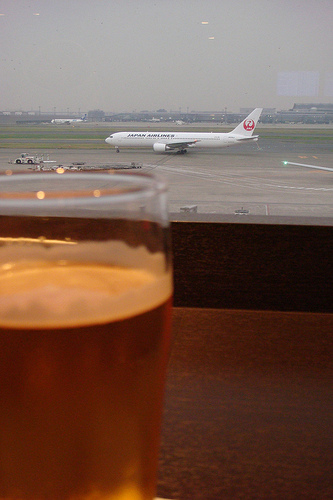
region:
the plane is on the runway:
[102, 113, 262, 160]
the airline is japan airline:
[114, 115, 260, 149]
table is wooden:
[200, 333, 314, 494]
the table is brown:
[207, 307, 317, 490]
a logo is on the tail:
[236, 115, 251, 131]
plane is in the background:
[34, 107, 91, 126]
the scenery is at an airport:
[17, 109, 320, 191]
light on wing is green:
[274, 155, 291, 165]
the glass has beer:
[4, 186, 173, 498]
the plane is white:
[102, 110, 262, 155]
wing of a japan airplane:
[219, 85, 332, 163]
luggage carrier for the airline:
[11, 142, 63, 163]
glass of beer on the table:
[13, 179, 198, 469]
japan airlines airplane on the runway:
[102, 103, 283, 172]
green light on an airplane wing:
[271, 146, 317, 197]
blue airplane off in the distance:
[12, 104, 111, 127]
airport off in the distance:
[84, 99, 233, 124]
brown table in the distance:
[185, 312, 297, 476]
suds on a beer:
[0, 249, 148, 317]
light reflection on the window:
[176, 12, 252, 60]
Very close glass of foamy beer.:
[1, 168, 174, 499]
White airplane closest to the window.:
[103, 106, 261, 155]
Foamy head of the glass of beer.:
[1, 243, 173, 327]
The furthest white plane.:
[48, 112, 89, 124]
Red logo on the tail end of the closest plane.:
[243, 118, 254, 131]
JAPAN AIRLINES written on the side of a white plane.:
[127, 132, 175, 138]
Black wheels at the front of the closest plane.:
[114, 149, 120, 153]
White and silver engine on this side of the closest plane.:
[151, 141, 174, 152]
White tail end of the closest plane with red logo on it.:
[232, 106, 262, 135]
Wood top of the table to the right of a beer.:
[155, 304, 331, 499]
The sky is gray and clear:
[38, 42, 190, 88]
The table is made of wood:
[229, 376, 304, 480]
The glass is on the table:
[16, 161, 221, 497]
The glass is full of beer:
[7, 182, 179, 495]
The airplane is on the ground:
[98, 103, 280, 157]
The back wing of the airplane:
[230, 101, 262, 139]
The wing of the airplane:
[158, 132, 198, 152]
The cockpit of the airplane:
[106, 131, 117, 141]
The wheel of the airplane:
[112, 145, 121, 154]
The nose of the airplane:
[102, 125, 119, 153]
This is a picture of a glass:
[9, 227, 185, 418]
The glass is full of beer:
[70, 315, 203, 459]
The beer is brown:
[60, 344, 209, 476]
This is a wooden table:
[208, 370, 310, 493]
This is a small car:
[23, 151, 62, 172]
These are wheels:
[14, 157, 48, 162]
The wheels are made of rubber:
[15, 159, 52, 163]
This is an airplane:
[111, 137, 239, 167]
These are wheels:
[111, 144, 134, 156]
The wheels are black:
[109, 148, 144, 156]